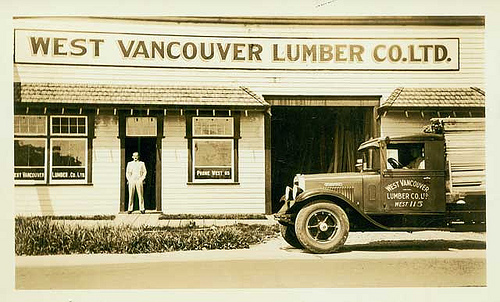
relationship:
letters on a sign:
[54, 50, 259, 90] [182, 162, 242, 184]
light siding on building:
[31, 93, 101, 121] [13, 17, 493, 262]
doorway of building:
[119, 129, 164, 214] [18, 0, 494, 232]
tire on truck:
[295, 200, 350, 251] [275, 132, 485, 250]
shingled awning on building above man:
[72, 72, 119, 122] [122, 149, 154, 211]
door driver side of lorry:
[381, 170, 432, 208] [273, 118, 486, 254]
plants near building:
[15, 223, 231, 251] [11, 14, 485, 220]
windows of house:
[13, 115, 89, 185] [16, 12, 486, 228]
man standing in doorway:
[120, 149, 150, 216] [121, 127, 161, 219]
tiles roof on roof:
[381, 86, 485, 111] [20, 78, 273, 119]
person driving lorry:
[410, 141, 427, 168] [273, 118, 486, 254]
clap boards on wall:
[162, 112, 188, 212] [8, 25, 478, 220]